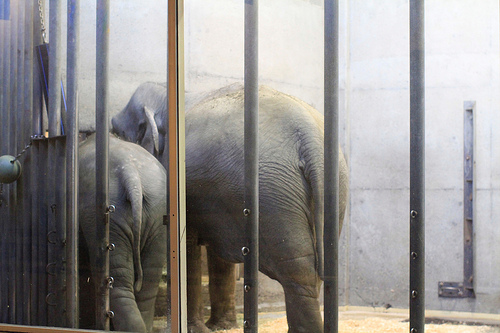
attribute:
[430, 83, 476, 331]
stick — small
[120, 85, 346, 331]
elephant — fat, one, gray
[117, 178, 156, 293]
tail — elephant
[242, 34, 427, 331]
bars — metal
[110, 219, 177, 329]
legs — hind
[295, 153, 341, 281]
tail — elephant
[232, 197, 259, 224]
ring — silver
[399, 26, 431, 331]
pole — metal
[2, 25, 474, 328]
fence — metal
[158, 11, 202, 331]
pole — metal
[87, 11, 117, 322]
pole — metal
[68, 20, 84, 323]
pole — metal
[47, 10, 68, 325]
pole — metal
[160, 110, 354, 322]
elephant — grey 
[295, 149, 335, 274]
tail — elephant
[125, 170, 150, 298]
tail — elephant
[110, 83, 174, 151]
head — animal, elephant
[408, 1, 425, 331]
rod — small, iron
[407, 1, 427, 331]
rod — iron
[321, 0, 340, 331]
rod — iron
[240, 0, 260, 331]
rod — iron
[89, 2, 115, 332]
rod — iron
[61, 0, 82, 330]
rod — iron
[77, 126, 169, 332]
elephant — gray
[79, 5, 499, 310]
wall — gray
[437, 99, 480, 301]
bar — metal